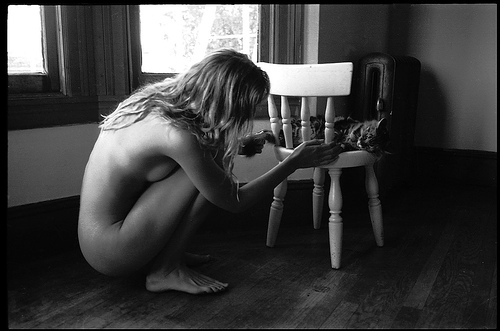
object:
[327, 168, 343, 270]
leg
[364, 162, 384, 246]
leg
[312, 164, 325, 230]
leg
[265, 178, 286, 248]
leg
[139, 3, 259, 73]
window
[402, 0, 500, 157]
wall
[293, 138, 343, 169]
hands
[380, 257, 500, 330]
rocks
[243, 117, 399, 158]
cat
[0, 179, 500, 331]
brown floor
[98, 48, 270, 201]
blonde hair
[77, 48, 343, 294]
lady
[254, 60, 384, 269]
chair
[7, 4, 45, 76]
window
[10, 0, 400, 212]
wall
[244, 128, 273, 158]
tail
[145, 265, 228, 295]
foot